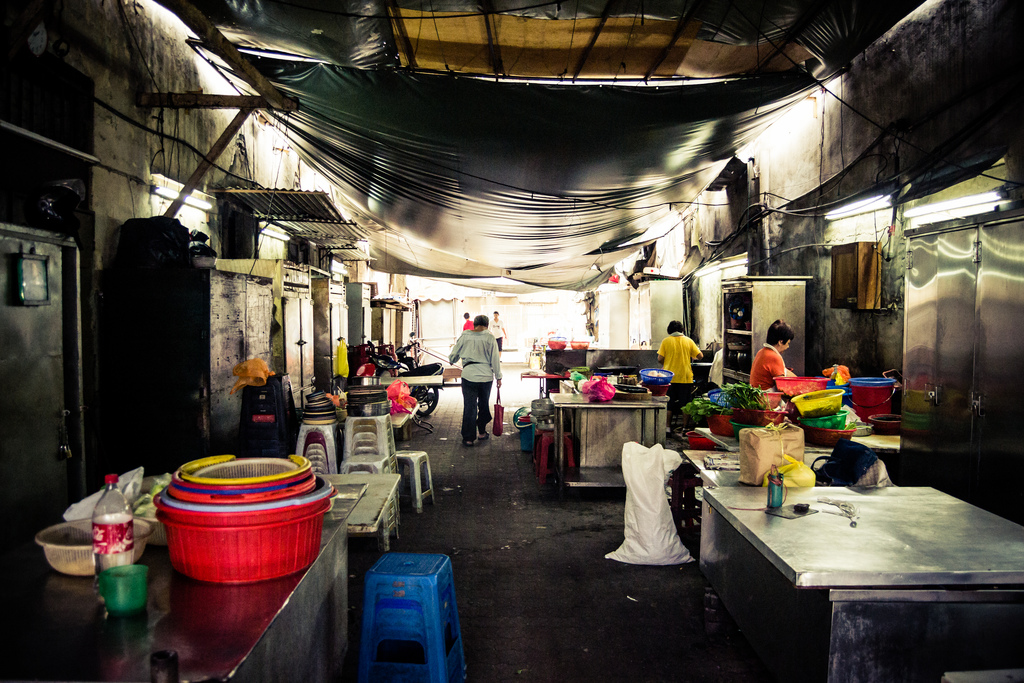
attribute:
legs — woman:
[459, 376, 488, 443]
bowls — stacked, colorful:
[145, 423, 334, 611]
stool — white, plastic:
[292, 400, 448, 509]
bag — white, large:
[603, 417, 714, 593]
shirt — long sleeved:
[435, 320, 526, 400]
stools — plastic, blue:
[355, 529, 470, 679]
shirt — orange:
[748, 350, 785, 385]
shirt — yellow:
[657, 339, 701, 381]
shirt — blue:
[450, 339, 509, 378]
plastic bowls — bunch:
[169, 400, 329, 595]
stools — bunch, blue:
[350, 517, 471, 677]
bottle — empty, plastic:
[72, 464, 161, 620]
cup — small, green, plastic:
[81, 555, 157, 622]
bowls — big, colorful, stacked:
[135, 423, 384, 631]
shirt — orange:
[746, 338, 785, 390]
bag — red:
[487, 376, 505, 437]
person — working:
[655, 318, 703, 403]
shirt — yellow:
[653, 325, 701, 384]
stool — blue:
[351, 545, 470, 679]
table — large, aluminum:
[3, 480, 375, 679]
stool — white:
[392, 441, 436, 511]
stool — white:
[336, 444, 391, 470]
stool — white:
[290, 413, 340, 474]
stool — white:
[340, 405, 397, 458]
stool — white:
[342, 426, 381, 450]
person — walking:
[444, 310, 503, 449]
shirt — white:
[444, 323, 501, 384]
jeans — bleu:
[458, 374, 495, 444]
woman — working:
[748, 314, 803, 395]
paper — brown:
[735, 420, 807, 485]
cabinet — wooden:
[828, 238, 887, 316]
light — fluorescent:
[821, 189, 893, 222]